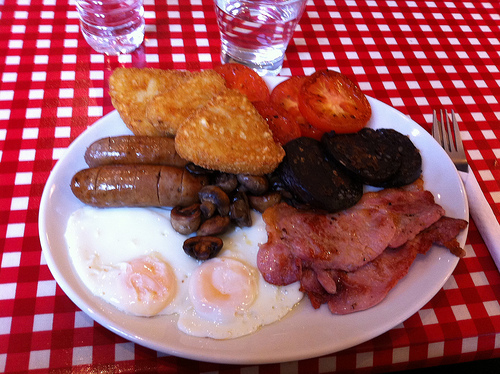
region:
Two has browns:
[101, 60, 293, 180]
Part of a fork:
[426, 102, 473, 249]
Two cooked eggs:
[62, 206, 318, 346]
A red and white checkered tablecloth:
[353, 10, 482, 75]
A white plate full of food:
[32, 52, 476, 364]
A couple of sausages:
[54, 122, 214, 214]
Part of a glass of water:
[217, 0, 298, 87]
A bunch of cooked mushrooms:
[157, 157, 281, 265]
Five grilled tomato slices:
[205, 57, 365, 153]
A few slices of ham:
[257, 179, 479, 319]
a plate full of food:
[25, 46, 467, 362]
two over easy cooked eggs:
[70, 195, 301, 334]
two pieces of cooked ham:
[260, 188, 491, 300]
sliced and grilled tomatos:
[227, 62, 364, 144]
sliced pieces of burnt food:
[270, 125, 432, 218]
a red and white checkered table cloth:
[10, 39, 497, 356]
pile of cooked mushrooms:
[162, 150, 284, 267]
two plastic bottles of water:
[64, 3, 336, 73]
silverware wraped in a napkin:
[419, 80, 498, 247]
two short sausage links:
[65, 125, 219, 218]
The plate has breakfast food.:
[47, 64, 444, 353]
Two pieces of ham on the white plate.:
[277, 178, 457, 297]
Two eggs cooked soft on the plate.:
[81, 196, 297, 336]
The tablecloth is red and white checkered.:
[375, 11, 487, 120]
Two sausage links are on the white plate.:
[80, 116, 234, 223]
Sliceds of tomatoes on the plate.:
[237, 32, 374, 144]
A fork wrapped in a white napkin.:
[441, 104, 499, 238]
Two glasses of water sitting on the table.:
[66, 7, 318, 72]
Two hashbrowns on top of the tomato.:
[113, 71, 275, 173]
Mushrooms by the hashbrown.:
[179, 181, 275, 238]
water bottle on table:
[68, 1, 155, 57]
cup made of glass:
[215, 0, 305, 72]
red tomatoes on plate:
[222, 56, 404, 170]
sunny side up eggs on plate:
[66, 206, 341, 338]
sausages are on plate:
[273, 131, 423, 216]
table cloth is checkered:
[1, 0, 497, 335]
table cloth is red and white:
[1, 1, 499, 311]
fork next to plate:
[426, 86, 497, 252]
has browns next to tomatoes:
[106, 51, 289, 196]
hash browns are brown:
[98, 55, 285, 185]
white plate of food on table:
[4, 10, 396, 372]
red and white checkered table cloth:
[32, 44, 447, 312]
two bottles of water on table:
[70, 2, 305, 79]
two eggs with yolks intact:
[84, 214, 281, 344]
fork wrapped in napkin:
[425, 64, 477, 246]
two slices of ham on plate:
[284, 188, 415, 310]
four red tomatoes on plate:
[218, 70, 342, 137]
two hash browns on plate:
[82, 65, 284, 173]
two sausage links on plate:
[54, 114, 204, 219]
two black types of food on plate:
[268, 122, 423, 210]